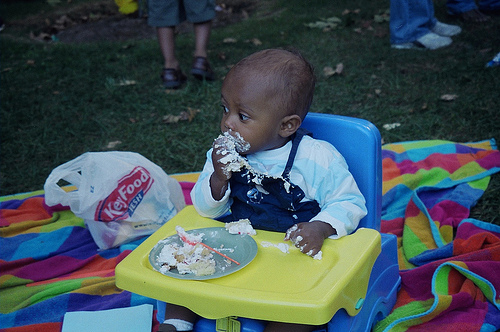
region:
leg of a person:
[142, 10, 186, 85]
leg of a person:
[192, 6, 234, 71]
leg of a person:
[391, 15, 446, 47]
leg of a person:
[429, 6, 446, 36]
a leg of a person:
[142, 32, 194, 101]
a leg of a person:
[179, 23, 229, 87]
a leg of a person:
[382, 8, 426, 57]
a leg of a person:
[427, 6, 447, 43]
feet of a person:
[161, 58, 188, 89]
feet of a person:
[194, 40, 238, 77]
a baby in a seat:
[120, 45, 405, 329]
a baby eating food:
[206, 128, 257, 180]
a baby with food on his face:
[204, 117, 258, 174]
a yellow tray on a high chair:
[117, 198, 386, 324]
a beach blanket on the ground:
[12, 131, 495, 325]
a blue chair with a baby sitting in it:
[309, 110, 417, 328]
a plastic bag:
[37, 147, 184, 238]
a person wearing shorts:
[141, 0, 223, 28]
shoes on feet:
[157, 55, 219, 87]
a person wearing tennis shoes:
[382, 19, 457, 52]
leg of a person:
[384, 18, 421, 55]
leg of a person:
[422, 6, 441, 23]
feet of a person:
[192, 60, 222, 92]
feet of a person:
[436, 13, 469, 34]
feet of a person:
[404, 28, 459, 60]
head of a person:
[195, 38, 356, 156]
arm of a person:
[191, 152, 257, 204]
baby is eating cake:
[151, 60, 340, 222]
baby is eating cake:
[188, 69, 283, 191]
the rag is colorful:
[26, 193, 133, 306]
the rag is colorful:
[9, 213, 106, 329]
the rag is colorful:
[376, 240, 486, 330]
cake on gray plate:
[159, 215, 254, 276]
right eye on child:
[214, 99, 231, 116]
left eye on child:
[235, 109, 255, 126]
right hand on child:
[207, 138, 240, 178]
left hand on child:
[281, 214, 333, 269]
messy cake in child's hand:
[206, 132, 255, 191]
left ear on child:
[280, 107, 303, 145]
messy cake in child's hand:
[276, 209, 328, 261]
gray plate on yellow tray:
[154, 219, 260, 286]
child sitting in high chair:
[171, 48, 393, 318]